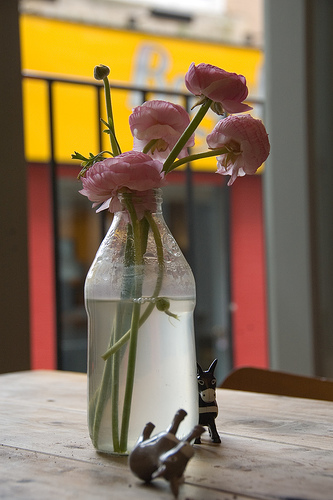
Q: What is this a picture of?
A: Flowers.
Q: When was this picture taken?
A: During the day.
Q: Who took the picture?
A: The photographer.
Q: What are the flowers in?
A: A bottle.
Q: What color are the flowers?
A: Pink.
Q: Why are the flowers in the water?
A: Flowers need water.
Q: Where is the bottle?
A: On the table.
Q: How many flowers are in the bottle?
A: 4.